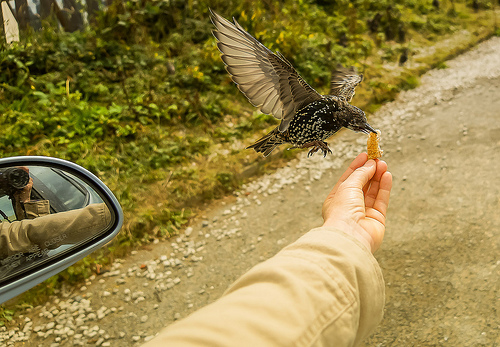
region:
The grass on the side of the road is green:
[31, 40, 233, 181]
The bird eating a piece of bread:
[206, 14, 389, 161]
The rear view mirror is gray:
[5, 135, 126, 310]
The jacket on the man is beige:
[141, 225, 420, 345]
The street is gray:
[408, 86, 487, 335]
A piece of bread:
[363, 128, 384, 161]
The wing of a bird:
[206, 5, 322, 132]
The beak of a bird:
[356, 120, 379, 136]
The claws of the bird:
[286, 134, 333, 160]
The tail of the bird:
[236, 126, 288, 161]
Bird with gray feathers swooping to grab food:
[168, 8, 389, 170]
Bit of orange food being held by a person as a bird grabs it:
[351, 114, 394, 187]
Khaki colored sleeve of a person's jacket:
[154, 189, 390, 344]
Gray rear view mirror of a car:
[0, 152, 158, 272]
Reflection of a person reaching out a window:
[0, 162, 132, 237]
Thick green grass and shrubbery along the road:
[125, 36, 283, 261]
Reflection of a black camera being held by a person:
[4, 159, 41, 206]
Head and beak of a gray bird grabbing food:
[345, 107, 386, 157]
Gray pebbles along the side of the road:
[126, 178, 252, 287]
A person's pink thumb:
[342, 151, 379, 206]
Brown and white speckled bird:
[207, 15, 380, 156]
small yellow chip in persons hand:
[364, 130, 386, 158]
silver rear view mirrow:
[2, 150, 122, 276]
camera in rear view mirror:
[1, 168, 36, 195]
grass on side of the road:
[1, 48, 213, 149]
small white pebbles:
[123, 255, 200, 292]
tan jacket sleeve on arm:
[192, 228, 394, 345]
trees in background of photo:
[5, 1, 103, 31]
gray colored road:
[415, 157, 497, 302]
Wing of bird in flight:
[209, 12, 321, 116]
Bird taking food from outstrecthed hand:
[201, 5, 406, 195]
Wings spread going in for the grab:
[207, 10, 391, 160]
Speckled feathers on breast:
[243, 97, 345, 157]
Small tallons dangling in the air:
[304, 139, 336, 162]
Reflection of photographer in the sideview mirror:
[0, 150, 125, 310]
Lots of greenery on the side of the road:
[4, 3, 491, 300]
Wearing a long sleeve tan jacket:
[110, 222, 415, 345]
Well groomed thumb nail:
[360, 155, 377, 170]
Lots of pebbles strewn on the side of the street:
[3, 134, 304, 345]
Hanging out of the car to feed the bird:
[2, 163, 118, 288]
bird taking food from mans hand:
[180, 13, 428, 198]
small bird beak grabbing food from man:
[352, 114, 387, 159]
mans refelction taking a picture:
[5, 149, 112, 257]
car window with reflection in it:
[19, 134, 139, 288]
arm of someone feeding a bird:
[236, 139, 418, 344]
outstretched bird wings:
[196, 14, 328, 118]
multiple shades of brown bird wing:
[192, 11, 335, 118]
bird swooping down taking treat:
[182, 18, 433, 253]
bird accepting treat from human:
[322, 100, 404, 177]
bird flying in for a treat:
[243, 53, 431, 204]